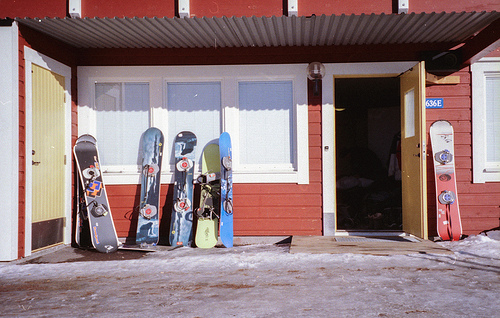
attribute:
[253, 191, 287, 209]
siding — red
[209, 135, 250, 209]
snowboard — propped, grey, gray, leaning, red, yellow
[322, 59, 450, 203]
door — open, closed, beige, brown, infront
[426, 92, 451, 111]
address — here, marked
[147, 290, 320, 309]
concrete — covered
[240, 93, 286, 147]
shades — drawn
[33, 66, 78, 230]
door — closed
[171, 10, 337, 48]
overhang — tin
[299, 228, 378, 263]
ramp — wooden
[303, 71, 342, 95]
light — mounted, next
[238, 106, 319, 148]
blinds — white, over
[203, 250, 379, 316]
cement — infront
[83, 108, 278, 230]
snowboards — leaning, against, vertical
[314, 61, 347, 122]
frame — around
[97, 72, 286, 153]
windows — three, white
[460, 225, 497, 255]
snow — piled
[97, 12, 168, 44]
roof — aluminum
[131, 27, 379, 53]
awning — over